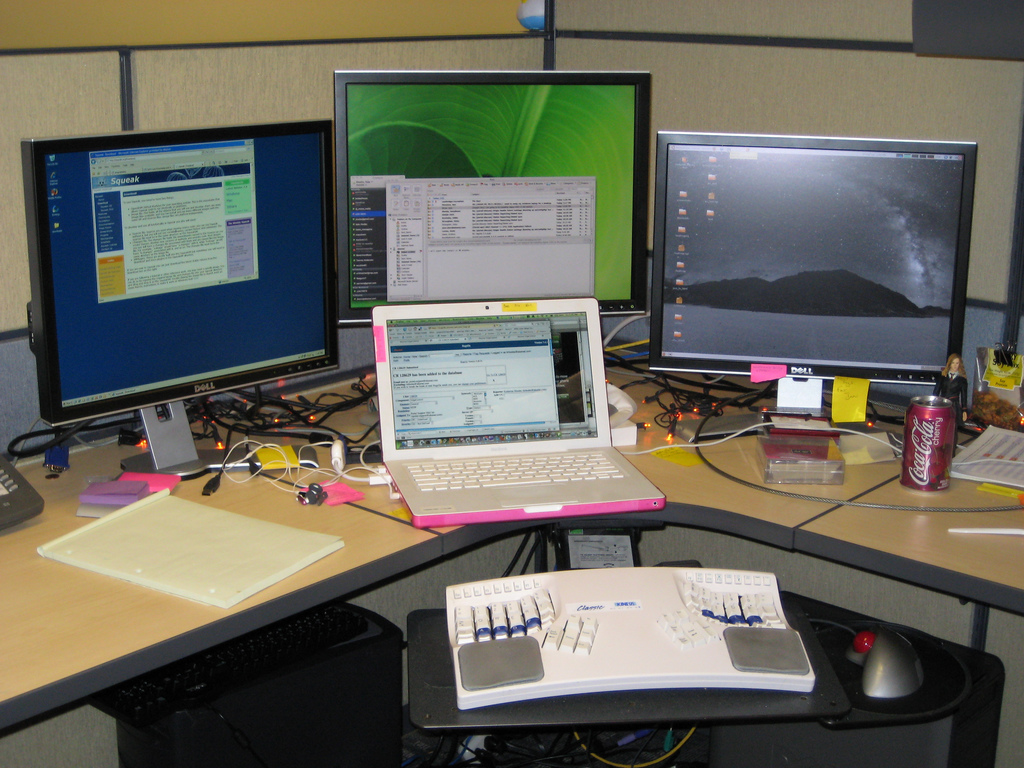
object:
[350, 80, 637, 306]
background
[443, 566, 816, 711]
white keyboard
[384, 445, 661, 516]
white keyboard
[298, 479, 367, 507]
pad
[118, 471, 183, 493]
pad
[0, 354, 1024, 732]
desk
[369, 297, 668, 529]
laptop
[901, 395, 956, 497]
can